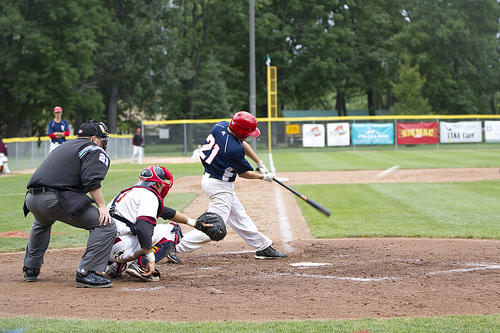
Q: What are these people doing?
A: Playing baseball.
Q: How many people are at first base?
A: Three.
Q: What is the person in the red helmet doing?
A: Batting.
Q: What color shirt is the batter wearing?
A: Blue.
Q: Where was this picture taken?
A: Baseball field.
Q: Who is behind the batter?
A: Catcher.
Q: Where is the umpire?
A: Behind catcher.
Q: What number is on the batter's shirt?
A: 21.